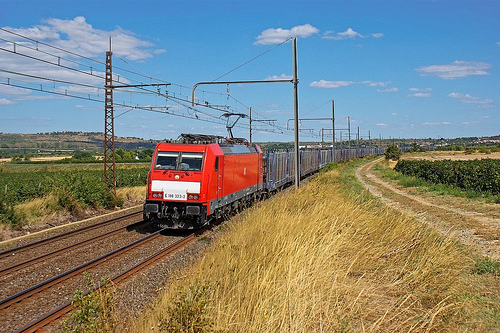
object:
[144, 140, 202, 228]
part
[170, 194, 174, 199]
number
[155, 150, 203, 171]
window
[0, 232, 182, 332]
track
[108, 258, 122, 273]
stones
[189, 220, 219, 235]
wheel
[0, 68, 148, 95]
wires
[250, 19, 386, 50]
clouds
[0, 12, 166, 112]
clouds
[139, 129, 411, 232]
train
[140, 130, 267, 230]
engine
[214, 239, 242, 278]
grass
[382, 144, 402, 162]
tree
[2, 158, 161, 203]
field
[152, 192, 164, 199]
headlight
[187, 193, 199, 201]
headlight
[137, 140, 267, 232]
car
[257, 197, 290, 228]
grass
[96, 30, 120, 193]
power pole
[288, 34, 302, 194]
poles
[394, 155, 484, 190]
growth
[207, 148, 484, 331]
field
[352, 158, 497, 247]
path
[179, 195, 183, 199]
numbers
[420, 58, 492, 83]
clouds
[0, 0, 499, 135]
sky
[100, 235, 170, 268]
gravel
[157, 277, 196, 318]
grass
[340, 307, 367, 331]
grass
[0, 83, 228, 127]
power cables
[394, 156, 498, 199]
hedges